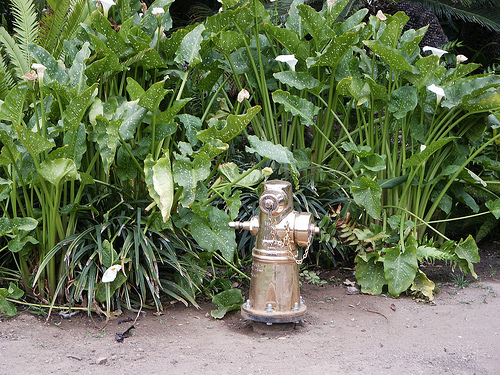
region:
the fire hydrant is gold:
[223, 178, 325, 332]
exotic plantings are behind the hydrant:
[6, 2, 498, 337]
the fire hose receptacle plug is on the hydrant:
[285, 208, 323, 255]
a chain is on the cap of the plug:
[281, 214, 321, 268]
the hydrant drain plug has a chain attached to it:
[255, 188, 285, 215]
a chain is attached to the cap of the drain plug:
[258, 193, 295, 245]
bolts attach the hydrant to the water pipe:
[237, 292, 310, 328]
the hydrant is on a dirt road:
[6, 271, 498, 371]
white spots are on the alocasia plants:
[31, 11, 497, 155]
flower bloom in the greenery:
[271, 49, 300, 69]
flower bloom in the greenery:
[101, 259, 121, 284]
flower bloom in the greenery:
[420, 82, 446, 98]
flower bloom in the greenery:
[28, 59, 47, 84]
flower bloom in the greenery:
[237, 87, 247, 101]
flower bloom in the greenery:
[421, 43, 449, 63]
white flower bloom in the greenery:
[276, 49, 300, 69]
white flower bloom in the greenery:
[414, 46, 451, 62]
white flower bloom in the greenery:
[91, 252, 123, 285]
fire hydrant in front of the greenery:
[221, 173, 326, 328]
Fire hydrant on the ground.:
[223, 165, 325, 330]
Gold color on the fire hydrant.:
[224, 177, 331, 329]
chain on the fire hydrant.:
[277, 220, 317, 268]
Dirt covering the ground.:
[1, 285, 498, 373]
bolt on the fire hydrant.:
[264, 300, 274, 327]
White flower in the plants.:
[421, 75, 447, 112]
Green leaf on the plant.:
[168, 144, 215, 209]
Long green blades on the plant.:
[30, 213, 205, 320]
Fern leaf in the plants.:
[7, 0, 43, 66]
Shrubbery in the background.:
[1, 0, 489, 322]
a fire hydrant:
[227, 173, 319, 326]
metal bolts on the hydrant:
[244, 293, 306, 321]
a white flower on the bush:
[96, 262, 126, 284]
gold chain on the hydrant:
[280, 232, 312, 265]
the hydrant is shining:
[231, 185, 316, 304]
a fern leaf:
[143, 152, 175, 221]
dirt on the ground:
[14, 283, 496, 372]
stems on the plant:
[360, 121, 449, 226]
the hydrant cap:
[293, 213, 316, 249]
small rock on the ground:
[93, 355, 110, 367]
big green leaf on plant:
[137, 150, 175, 223]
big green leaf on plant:
[189, 206, 236, 263]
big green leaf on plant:
[169, 146, 213, 211]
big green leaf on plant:
[196, 102, 263, 155]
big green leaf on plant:
[138, 72, 173, 121]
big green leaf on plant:
[156, 95, 191, 130]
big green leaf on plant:
[33, 158, 81, 186]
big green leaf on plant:
[57, 80, 101, 135]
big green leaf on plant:
[8, 116, 54, 158]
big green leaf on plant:
[4, 83, 32, 123]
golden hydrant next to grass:
[186, 159, 358, 324]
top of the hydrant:
[222, 166, 329, 235]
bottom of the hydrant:
[202, 269, 329, 349]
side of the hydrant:
[276, 200, 327, 295]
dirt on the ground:
[312, 300, 419, 364]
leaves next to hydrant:
[328, 153, 470, 303]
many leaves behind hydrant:
[18, 21, 453, 202]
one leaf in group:
[134, 145, 189, 232]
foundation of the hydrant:
[225, 276, 335, 348]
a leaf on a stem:
[33, 153, 86, 193]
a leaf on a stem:
[204, 282, 243, 317]